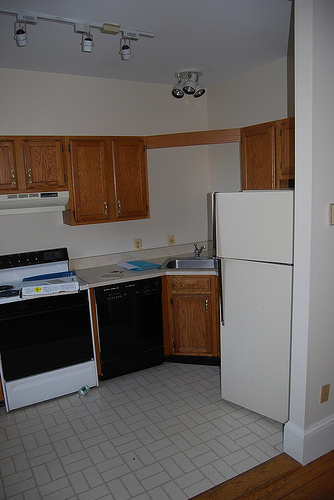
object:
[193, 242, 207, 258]
tap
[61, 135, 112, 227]
cupboards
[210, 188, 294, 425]
refrigerator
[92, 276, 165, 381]
dishwasher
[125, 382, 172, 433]
tiles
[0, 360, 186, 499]
floor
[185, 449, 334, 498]
floor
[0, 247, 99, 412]
stove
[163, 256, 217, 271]
sink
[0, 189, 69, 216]
exhaust fan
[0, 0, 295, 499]
kitchen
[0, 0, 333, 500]
house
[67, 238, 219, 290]
countertop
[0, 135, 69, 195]
cabinets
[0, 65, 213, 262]
wall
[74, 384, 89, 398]
bottle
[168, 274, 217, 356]
door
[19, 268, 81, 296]
pizza box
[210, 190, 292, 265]
freezer door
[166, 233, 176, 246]
light switch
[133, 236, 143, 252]
outlet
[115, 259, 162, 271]
book